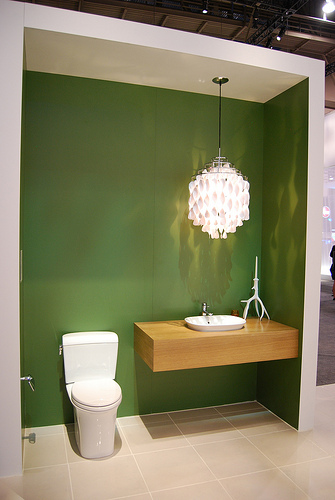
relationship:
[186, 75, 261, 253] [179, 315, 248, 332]
lamp over sink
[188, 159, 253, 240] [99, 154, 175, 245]
chandelier on wall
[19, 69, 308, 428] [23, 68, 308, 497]
walls of bathroom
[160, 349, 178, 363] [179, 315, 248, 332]
wood with a sink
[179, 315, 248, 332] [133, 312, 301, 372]
sink on a shelf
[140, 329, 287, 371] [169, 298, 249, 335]
counter of sink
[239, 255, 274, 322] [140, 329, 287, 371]
decoration on counter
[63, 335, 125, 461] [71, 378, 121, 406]
toilet has lid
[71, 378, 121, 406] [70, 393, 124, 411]
lid on toilet seat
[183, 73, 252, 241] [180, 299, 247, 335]
hanging light over sink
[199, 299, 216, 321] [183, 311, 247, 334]
faucet on sink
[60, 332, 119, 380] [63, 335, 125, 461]
tank on toilet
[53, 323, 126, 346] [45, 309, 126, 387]
lid on tank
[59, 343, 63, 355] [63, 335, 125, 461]
handle on toilet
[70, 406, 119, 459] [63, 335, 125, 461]
toilet base on toilet